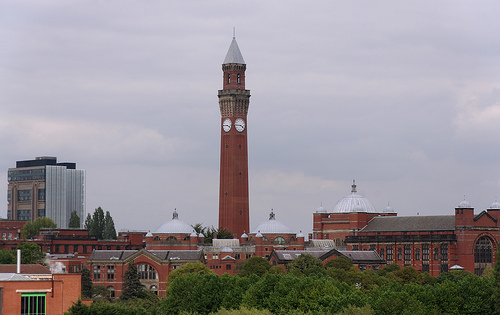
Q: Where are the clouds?
A: In the sky.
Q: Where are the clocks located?
A: On the tall red tower.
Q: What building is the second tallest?
A: The one that is farthest away.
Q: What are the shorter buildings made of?
A: Brick.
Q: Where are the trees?
A: In front of the buildings.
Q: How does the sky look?
A: Cloudy.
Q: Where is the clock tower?
A: In the middle of the buildings.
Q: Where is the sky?
A: Above the buildings.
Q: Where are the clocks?
A: On the tower.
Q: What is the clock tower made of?
A: Brick.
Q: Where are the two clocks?
A: On the tower.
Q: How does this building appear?
A: Cathedral styled.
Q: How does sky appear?
A: Foggy.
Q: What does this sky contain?
A: Clouds.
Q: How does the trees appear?
A: Green.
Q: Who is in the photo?
A: No one.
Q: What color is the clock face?
A: White.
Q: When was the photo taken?
A: Afternoon.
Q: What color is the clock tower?
A: Red.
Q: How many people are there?
A: None.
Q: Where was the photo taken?
A: In a city.